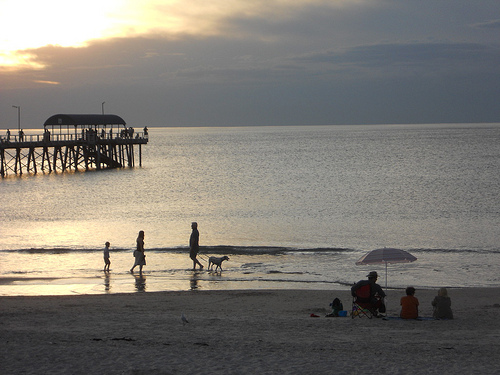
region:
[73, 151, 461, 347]
people enjoying sunset at beach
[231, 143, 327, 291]
ocean looks like silver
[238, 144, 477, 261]
water is calm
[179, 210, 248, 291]
man walking dog in shallow surf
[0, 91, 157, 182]
pier overlooking the water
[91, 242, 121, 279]
small child walking in water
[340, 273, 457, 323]
three people sitting on the sand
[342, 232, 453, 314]
one opened umbrellas above the people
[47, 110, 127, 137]
part of the pier has a roof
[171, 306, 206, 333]
seagull walking on the sand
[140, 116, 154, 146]
Man standing on end of pier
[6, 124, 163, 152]
People standing on a pier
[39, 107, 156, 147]
Canopy over pier for shade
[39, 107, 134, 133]
Canopy over pier is black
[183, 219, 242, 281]
Man walking dog on beach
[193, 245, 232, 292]
Dog is on a leash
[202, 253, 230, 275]
White dog walking on beach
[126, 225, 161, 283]
Woman walking on beach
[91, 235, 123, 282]
Child walking on beach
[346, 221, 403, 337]
Man sitting in beach chair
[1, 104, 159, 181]
Pier jutting out into the water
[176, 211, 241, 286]
Man with a dog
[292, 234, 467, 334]
People sitting under an umbrella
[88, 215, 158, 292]
Woman and child in the water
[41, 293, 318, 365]
Sand on a beach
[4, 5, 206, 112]
Sun behind the clouds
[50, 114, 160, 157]
People out on a pier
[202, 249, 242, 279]
Dog in the water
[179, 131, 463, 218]
Calm water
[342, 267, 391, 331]
Man sitting in a chair on the beach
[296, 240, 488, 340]
family on the beach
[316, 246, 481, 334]
family under an umbrella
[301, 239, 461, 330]
family watching a sunset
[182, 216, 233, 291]
man walking a dog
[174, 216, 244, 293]
man and his dog on the beach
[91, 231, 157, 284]
woman and child on the beach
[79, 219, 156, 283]
woman and child wading in the water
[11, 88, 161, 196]
pier on the beach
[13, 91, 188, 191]
covered pier at sunset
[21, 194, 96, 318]
sunset shining on the water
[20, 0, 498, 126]
dark clouds on the horizon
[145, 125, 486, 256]
the ocean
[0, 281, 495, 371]
the shore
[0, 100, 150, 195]
a pier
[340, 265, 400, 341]
person sitting in a chair on the beach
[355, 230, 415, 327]
a large white open umbrella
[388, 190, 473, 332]
people sitting on the sand and facing the water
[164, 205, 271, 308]
man and dog on the shore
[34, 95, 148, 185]
canopy over a section of pier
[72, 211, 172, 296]
adult and child walking near small waves on shore